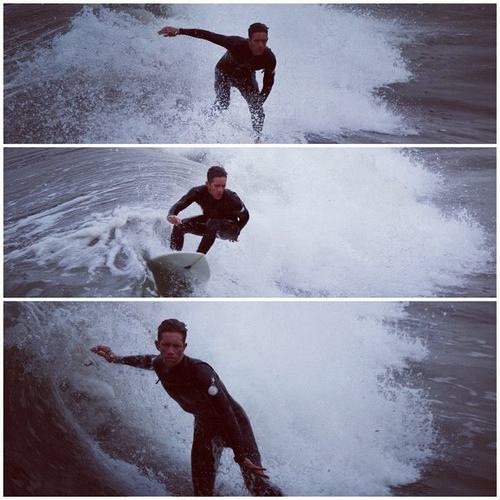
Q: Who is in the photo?
A: A man.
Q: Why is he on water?
A: Surfing.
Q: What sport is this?
A: Surfing.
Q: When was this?
A: Daytime.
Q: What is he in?
A: A costume.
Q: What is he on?
A: A surfboard.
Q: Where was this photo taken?
A: On a beach.